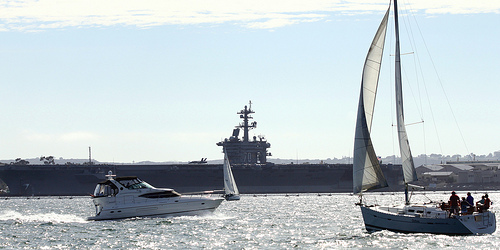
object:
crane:
[88, 146, 92, 162]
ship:
[83, 170, 226, 221]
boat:
[87, 170, 225, 221]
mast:
[391, 0, 409, 205]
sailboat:
[351, 0, 497, 237]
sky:
[0, 0, 495, 163]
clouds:
[0, 1, 500, 34]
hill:
[6, 157, 160, 179]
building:
[416, 163, 443, 178]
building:
[421, 170, 457, 185]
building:
[442, 163, 474, 183]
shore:
[406, 181, 498, 191]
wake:
[12, 207, 86, 231]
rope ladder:
[391, 0, 426, 190]